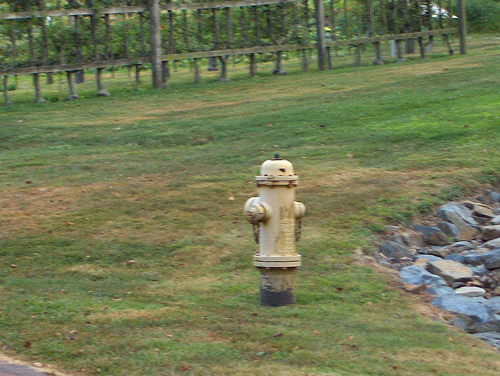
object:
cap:
[242, 200, 269, 225]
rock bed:
[366, 185, 499, 353]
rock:
[429, 259, 472, 282]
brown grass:
[3, 187, 183, 248]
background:
[2, 0, 499, 105]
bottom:
[254, 260, 300, 306]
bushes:
[6, 0, 259, 131]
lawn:
[323, 99, 470, 162]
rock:
[402, 258, 443, 293]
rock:
[431, 291, 495, 327]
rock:
[440, 196, 480, 239]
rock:
[479, 247, 498, 265]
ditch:
[362, 187, 499, 352]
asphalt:
[0, 351, 47, 374]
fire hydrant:
[241, 150, 307, 305]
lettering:
[277, 204, 299, 253]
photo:
[347, 112, 405, 168]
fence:
[2, 27, 466, 104]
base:
[258, 261, 297, 308]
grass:
[78, 108, 443, 176]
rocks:
[421, 222, 459, 244]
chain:
[292, 217, 303, 245]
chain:
[248, 221, 261, 243]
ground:
[2, 36, 497, 373]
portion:
[21, 357, 33, 366]